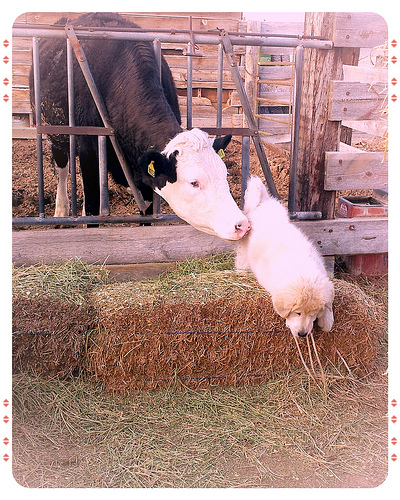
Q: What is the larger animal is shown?
A: A Cow.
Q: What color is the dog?
A: White.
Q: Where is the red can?
A: Center right.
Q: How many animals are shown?
A: Two.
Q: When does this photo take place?
A: Daytime.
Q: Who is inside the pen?
A: The cow.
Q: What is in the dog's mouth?
A: Hay.